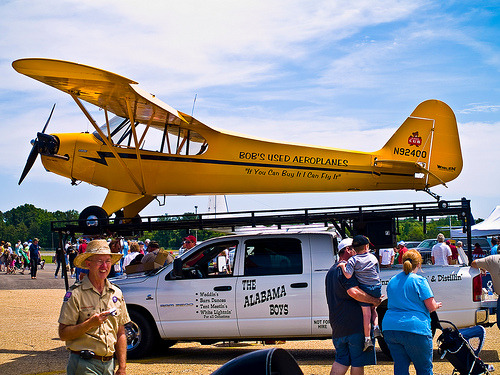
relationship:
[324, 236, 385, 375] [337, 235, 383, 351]
man holding child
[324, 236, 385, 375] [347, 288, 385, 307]
man has arms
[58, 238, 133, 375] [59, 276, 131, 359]
man in uniform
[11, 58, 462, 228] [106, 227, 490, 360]
plane on top of truck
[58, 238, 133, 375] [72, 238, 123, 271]
man in cowboy hat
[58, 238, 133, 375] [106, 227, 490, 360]
man in front of pick up truck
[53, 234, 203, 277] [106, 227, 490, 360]
crowd standing behind pick up truck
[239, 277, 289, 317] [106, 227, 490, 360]
writing on pick up truck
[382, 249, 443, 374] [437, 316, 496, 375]
woman pushing stroller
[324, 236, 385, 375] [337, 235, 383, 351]
man carrying child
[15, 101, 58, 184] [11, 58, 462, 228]
propeller on airplane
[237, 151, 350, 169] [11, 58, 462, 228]
writing on airplane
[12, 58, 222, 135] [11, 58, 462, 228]
wing on airplane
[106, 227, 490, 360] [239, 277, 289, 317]
pick up truck has letters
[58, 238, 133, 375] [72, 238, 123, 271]
man wearing hat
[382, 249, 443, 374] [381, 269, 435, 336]
woman wearing shirt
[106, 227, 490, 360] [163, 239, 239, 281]
pick up truck has window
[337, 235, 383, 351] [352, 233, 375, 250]
child wearing hat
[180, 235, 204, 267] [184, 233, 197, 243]
man wearing hat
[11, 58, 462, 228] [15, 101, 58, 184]
airplane has propeller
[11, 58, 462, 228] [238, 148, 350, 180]
airplane has advertisement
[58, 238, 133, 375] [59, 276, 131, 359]
man wearing uniform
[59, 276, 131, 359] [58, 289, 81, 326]
uniform has sleeve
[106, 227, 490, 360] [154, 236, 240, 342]
pick up truck has door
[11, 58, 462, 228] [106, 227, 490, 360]
airplane attached to top of pick up truck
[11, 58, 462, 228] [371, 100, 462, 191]
airplane has tail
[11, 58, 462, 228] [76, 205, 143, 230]
airplane has wheels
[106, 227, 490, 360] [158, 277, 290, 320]
pick up truck has advertisement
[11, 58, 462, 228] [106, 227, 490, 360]
airplane on top of pick up truck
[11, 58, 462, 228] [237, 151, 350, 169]
airplane with lettering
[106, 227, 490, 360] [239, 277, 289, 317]
pick up truck with lettering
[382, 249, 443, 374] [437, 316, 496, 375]
woman pushing carriage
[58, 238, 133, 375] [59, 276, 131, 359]
man wearing shirt